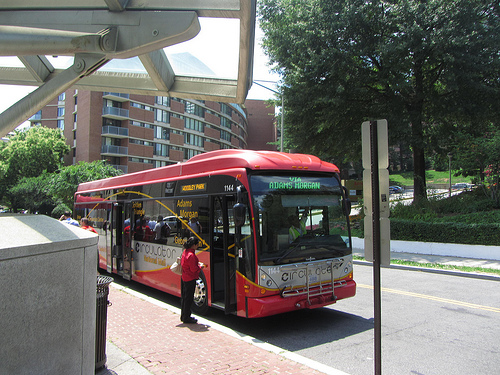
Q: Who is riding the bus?
A: A woman.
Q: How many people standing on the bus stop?
A: Three.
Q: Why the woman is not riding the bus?
A: Asking the driver.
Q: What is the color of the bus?
A: Red and black.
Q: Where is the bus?
A: At the bus stop.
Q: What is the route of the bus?
A: Adams Morgan.